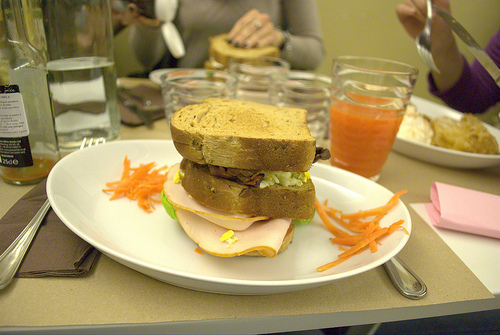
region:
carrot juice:
[319, 50, 421, 185]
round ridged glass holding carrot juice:
[319, 46, 427, 186]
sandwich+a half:
[149, 78, 327, 259]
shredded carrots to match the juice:
[100, 146, 419, 276]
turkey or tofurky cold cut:
[157, 160, 292, 261]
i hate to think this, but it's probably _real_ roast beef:
[183, 134, 333, 189]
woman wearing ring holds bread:
[200, 4, 292, 74]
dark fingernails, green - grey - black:
[217, 30, 265, 53]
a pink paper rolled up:
[412, 166, 499, 240]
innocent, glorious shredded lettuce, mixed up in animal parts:
[153, 166, 324, 263]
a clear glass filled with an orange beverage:
[329, 54, 416, 179]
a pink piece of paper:
[429, 181, 498, 240]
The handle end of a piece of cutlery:
[384, 257, 429, 302]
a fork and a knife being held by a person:
[415, 3, 498, 78]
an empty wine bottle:
[0, 10, 58, 181]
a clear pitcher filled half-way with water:
[5, 3, 122, 153]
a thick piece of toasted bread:
[169, 97, 317, 169]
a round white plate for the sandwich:
[46, 139, 410, 296]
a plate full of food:
[391, 94, 498, 169]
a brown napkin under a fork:
[4, 179, 97, 276]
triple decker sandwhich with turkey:
[154, 75, 326, 265]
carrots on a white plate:
[324, 188, 410, 269]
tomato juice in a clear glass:
[326, 46, 431, 177]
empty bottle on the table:
[4, 15, 60, 191]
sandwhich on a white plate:
[29, 98, 419, 290]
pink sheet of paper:
[429, 168, 499, 241]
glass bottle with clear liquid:
[37, 23, 146, 136]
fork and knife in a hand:
[414, 2, 498, 105]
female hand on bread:
[217, 7, 302, 64]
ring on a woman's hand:
[251, 18, 265, 33]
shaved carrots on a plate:
[112, 141, 157, 209]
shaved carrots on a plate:
[317, 200, 386, 264]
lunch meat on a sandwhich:
[164, 168, 290, 263]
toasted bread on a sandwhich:
[196, 93, 275, 158]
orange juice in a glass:
[327, 91, 407, 191]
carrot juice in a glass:
[330, 47, 417, 184]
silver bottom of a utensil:
[389, 253, 437, 313]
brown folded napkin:
[29, 242, 90, 280]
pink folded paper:
[432, 176, 476, 231]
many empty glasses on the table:
[173, 38, 365, 155]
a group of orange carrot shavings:
[311, 187, 404, 275]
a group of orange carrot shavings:
[102, 153, 169, 212]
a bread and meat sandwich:
[166, 95, 321, 262]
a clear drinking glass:
[330, 53, 417, 178]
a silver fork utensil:
[0, 133, 107, 291]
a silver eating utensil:
[383, 254, 426, 299]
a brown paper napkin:
[4, 173, 96, 281]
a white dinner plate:
[46, 140, 414, 297]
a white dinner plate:
[391, 92, 498, 167]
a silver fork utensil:
[415, 3, 440, 75]